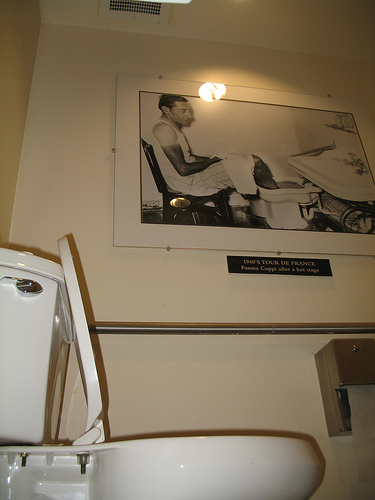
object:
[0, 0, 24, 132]
wall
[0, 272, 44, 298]
flusher handle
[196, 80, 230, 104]
light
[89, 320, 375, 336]
metal bar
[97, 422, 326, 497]
seat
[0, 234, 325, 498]
clean toilet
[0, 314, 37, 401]
white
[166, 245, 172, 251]
screw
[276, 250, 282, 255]
screw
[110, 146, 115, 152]
screw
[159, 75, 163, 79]
screw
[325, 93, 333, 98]
screw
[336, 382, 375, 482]
toilet paper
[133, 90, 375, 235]
photograph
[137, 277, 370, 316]
wall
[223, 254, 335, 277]
sign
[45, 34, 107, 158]
wall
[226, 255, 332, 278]
poster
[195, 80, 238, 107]
reflection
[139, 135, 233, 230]
chair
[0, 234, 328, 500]
toilet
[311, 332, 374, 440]
shelf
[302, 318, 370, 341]
railing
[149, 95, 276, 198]
athlete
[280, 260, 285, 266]
letters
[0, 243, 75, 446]
tank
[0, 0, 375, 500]
public restroom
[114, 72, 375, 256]
glass